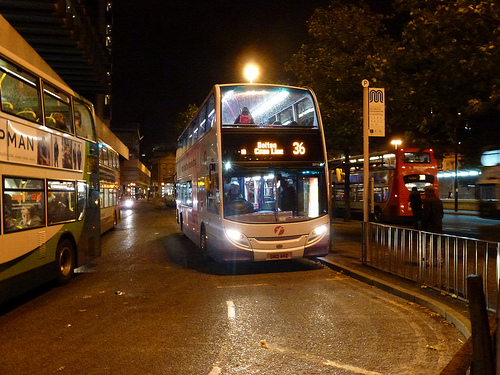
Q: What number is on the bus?
A: 36.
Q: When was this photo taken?
A: It was taken at night.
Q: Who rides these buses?
A: Local residents.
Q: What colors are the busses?
A: White, red, green.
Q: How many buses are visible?
A: 4.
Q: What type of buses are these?
A: Double deckers.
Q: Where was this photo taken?
A: England.